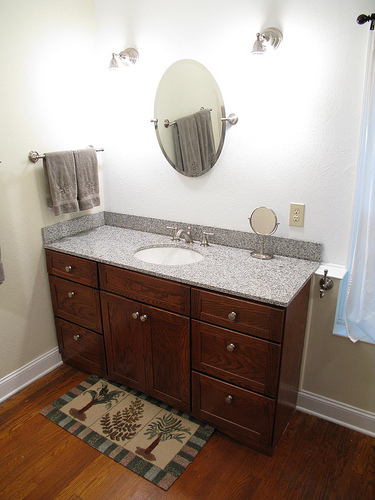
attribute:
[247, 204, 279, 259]
mirror — round, silver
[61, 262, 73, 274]
knob — silver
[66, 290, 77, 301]
knob — silver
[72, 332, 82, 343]
knob — silver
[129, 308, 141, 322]
knob — silver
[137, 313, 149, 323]
knob — silver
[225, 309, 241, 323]
knob — silver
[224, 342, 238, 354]
knob — silver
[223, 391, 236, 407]
knob — silver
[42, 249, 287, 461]
cabinet — closed, wooden, brown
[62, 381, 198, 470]
pattern — leaf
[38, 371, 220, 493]
rug — decorative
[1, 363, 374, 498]
floor — wooden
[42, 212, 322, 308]
countertop — granite, gray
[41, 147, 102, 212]
towels — beige, hanging, gray, small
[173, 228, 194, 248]
faucet — chrome, silver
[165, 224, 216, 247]
handles — chrome, closed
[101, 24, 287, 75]
lights — shining, silver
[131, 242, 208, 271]
sink — white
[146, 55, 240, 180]
mirror — wide, oval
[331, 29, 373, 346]
curtain — white, shear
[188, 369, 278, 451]
drawer — wooden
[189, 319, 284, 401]
drawer — wooden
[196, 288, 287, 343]
drawer — wooden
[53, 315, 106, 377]
drawer — wooden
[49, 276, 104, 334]
drawer — wooden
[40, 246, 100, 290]
drawer — wooden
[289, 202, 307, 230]
outlet — electrical, cream colored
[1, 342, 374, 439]
baseboards — bright white